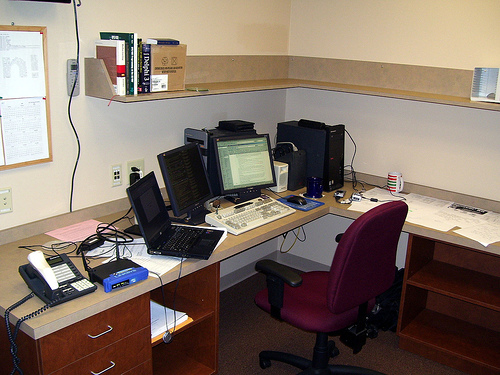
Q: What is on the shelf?
A: Books.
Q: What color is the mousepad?
A: Blue.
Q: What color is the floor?
A: Brown.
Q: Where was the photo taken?
A: An office.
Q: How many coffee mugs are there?
A: 1.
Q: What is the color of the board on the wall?
A: White.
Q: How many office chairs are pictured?
A: 1.